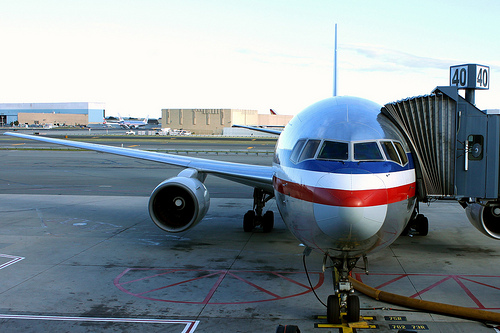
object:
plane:
[2, 20, 429, 324]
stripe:
[270, 174, 418, 208]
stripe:
[269, 148, 417, 175]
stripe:
[271, 162, 417, 192]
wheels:
[325, 294, 341, 324]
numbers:
[452, 68, 461, 87]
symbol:
[113, 265, 326, 305]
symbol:
[355, 273, 500, 312]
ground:
[0, 125, 500, 332]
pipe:
[343, 271, 500, 325]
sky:
[0, 0, 499, 118]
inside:
[289, 139, 409, 166]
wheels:
[242, 209, 257, 232]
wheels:
[415, 213, 428, 237]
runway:
[0, 135, 282, 163]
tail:
[231, 23, 339, 137]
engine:
[146, 168, 213, 235]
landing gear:
[326, 251, 365, 322]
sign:
[449, 64, 491, 90]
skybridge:
[375, 85, 500, 201]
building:
[159, 107, 258, 134]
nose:
[311, 168, 389, 243]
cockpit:
[288, 137, 408, 167]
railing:
[140, 147, 276, 157]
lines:
[273, 267, 321, 275]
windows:
[289, 137, 308, 164]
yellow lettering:
[390, 315, 403, 321]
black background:
[383, 315, 409, 321]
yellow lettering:
[391, 324, 425, 330]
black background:
[389, 323, 429, 331]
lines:
[0, 313, 186, 324]